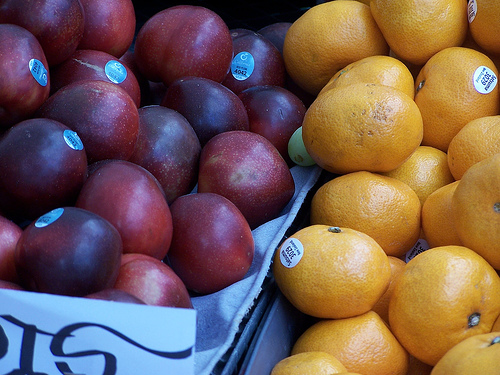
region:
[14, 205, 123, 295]
single red plum in a crate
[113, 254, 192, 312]
single red plum in a crate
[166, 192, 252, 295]
single red plum in a crate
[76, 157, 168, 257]
single red plum in a crate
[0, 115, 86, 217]
single red plum in a crate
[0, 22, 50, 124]
single red plum in a crate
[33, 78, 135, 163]
single red plum in a crate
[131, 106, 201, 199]
single red plum in a crate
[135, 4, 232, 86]
single red plum in a crate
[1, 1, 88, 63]
dark red colored fruit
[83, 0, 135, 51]
dark red colored fruit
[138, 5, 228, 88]
dark red colored fruit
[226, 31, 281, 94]
dark red colored fruit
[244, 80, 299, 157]
dark red colored fruit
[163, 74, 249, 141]
dark red colored fruit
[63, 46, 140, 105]
dark red colored fruit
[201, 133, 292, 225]
dark red colored fruit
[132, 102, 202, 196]
dark red colored fruit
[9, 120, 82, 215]
dark red colored fruit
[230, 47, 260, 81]
sticker on the apple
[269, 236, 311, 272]
sticker on the orange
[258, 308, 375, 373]
oranges in the box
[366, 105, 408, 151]
bruises on the orange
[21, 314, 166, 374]
writing on the box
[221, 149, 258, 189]
the apple is red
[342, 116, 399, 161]
the orange is orange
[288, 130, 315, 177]
the grape is green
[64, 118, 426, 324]
the fruit in cartons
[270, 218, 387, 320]
light orange colored fruit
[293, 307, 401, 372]
light orange colored fruit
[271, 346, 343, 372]
light orange colored fruit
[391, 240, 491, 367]
light orange colored fruit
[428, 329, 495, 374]
light orange colored fruit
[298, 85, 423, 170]
light orange colored fruit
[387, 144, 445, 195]
light orange colored fruit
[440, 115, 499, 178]
light orange colored fruit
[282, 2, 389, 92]
light orange colored fruit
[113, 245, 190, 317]
piece of ripe fruit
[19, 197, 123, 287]
piece of ripe fruit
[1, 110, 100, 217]
piece of ripe fruit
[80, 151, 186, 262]
piece of ripe fruit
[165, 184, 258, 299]
piece of ripe fruit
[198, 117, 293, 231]
piece of ripe fruit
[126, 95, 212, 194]
piece of ripe fruit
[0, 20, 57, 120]
piece of ripe fruit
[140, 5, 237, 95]
piece of ripe fruit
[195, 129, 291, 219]
a ripe red apple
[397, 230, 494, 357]
a ripe orange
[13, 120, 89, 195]
a apple with a sticker on it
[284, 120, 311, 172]
a green grape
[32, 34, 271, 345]
several ripe red apples in a crate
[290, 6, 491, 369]
several oranges in a pile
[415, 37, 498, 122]
a orange with a sticker on it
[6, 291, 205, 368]
a piece of paper with writing on it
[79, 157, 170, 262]
fruit is bright red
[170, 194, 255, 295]
fruit is bright red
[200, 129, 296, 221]
fruit is bright red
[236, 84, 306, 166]
fruit is bright red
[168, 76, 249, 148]
fruit is bright red